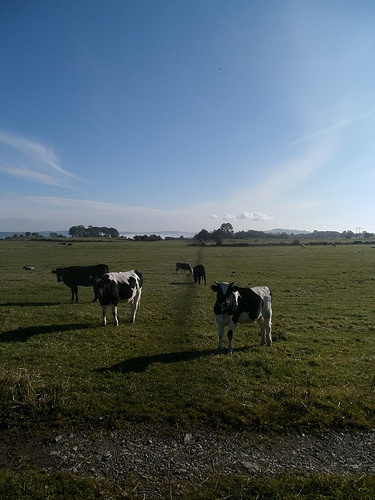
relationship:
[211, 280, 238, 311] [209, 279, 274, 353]
head of a cow